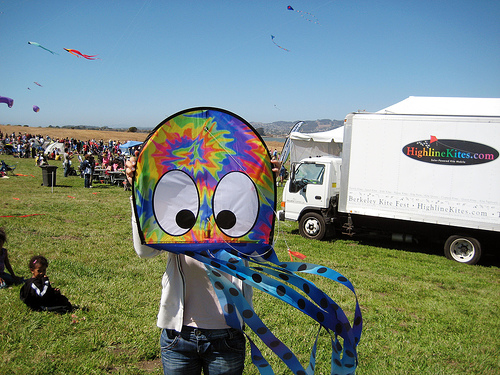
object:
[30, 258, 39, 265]
bow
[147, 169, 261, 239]
big eyes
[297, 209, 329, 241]
front tire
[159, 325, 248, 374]
jeans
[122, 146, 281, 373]
person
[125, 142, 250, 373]
woman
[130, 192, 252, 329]
shirt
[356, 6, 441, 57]
blue skies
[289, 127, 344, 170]
shelter tent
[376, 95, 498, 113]
shelter tent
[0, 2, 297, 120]
kites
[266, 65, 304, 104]
ground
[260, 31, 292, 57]
kite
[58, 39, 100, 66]
kite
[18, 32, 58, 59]
kite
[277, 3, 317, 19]
kite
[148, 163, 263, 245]
eyeballs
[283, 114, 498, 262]
white truck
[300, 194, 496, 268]
tires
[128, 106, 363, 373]
kite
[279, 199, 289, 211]
orange light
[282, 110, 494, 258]
truck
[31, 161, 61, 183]
trash can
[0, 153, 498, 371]
grass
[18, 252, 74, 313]
girl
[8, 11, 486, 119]
sky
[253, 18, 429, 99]
mountain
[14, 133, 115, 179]
crowd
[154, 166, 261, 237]
eyes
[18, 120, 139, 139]
field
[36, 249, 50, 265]
hair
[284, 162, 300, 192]
mirror